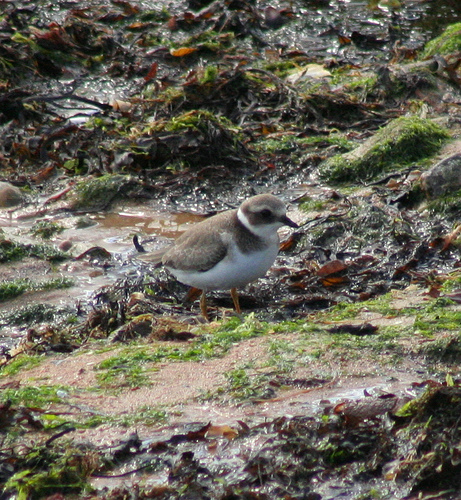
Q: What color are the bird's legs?
A: Orange.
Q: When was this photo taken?
A: During the day.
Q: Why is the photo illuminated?
A: Sunlight.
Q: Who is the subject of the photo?
A: The bird.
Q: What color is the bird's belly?
A: White.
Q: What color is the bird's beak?
A: Black.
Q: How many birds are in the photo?
A: One.